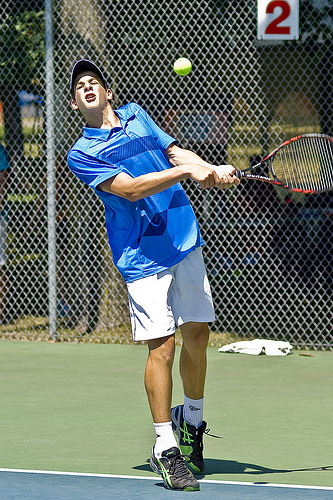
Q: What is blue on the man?
A: The shirt.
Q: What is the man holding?
A: A tennis racket.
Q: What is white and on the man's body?
A: The man's shorts.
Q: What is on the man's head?
A: Hat.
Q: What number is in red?
A: 2.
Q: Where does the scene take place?
A: On a tennis court.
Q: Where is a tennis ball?
A: In the air.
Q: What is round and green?
A: Tennis ball.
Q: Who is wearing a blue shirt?
A: Tennis player.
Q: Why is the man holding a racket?
A: To play tennis.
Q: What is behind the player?
A: A fence.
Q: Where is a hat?
A: On player's head.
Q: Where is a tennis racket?
A: In man's hands.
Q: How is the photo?
A: Clear.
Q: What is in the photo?
A: A man.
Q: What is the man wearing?
A: Clothes.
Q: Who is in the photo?
A: A person.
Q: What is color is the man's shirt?
A: Blue.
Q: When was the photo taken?
A: Daytime.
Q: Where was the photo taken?
A: Tennis court.